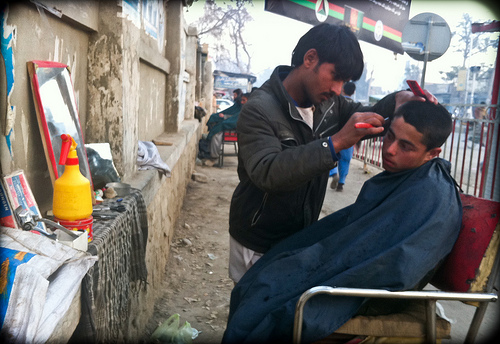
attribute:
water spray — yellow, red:
[52, 133, 92, 240]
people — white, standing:
[238, 35, 463, 302]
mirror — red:
[29, 61, 95, 205]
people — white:
[199, 63, 491, 310]